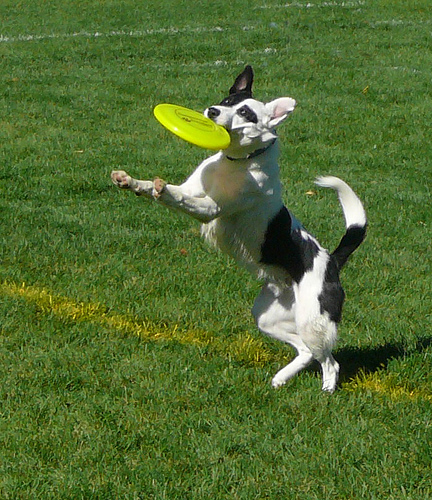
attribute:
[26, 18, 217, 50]
stripe — white, painted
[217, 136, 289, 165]
black collar — black 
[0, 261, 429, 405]
stripe — yellow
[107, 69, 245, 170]
frisbee — elongated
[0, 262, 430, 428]
line — yellow 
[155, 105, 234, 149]
frisbee — yellow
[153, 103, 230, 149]
frisbee — round, yellow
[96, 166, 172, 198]
pad — pink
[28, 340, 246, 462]
grass — green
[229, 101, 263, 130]
patch — black